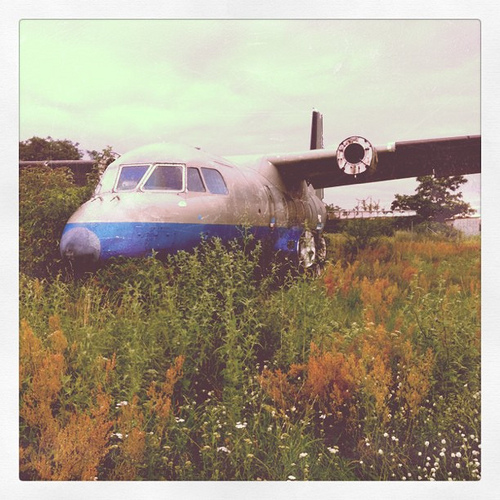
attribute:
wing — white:
[256, 125, 491, 203]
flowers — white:
[436, 453, 446, 459]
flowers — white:
[446, 450, 456, 456]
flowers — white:
[421, 459, 426, 472]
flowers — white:
[471, 457, 475, 465]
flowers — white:
[235, 421, 245, 431]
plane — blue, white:
[24, 107, 471, 266]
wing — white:
[258, 101, 486, 219]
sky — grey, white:
[20, 20, 474, 155]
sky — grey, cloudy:
[19, 18, 481, 217]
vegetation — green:
[23, 246, 470, 470]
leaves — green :
[391, 176, 472, 218]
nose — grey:
[40, 207, 132, 289]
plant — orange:
[260, 316, 440, 443]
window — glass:
[140, 166, 227, 196]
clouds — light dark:
[100, 48, 410, 107]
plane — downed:
[37, 51, 407, 332]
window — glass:
[130, 163, 185, 201]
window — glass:
[181, 162, 225, 198]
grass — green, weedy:
[17, 247, 274, 409]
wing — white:
[282, 120, 477, 190]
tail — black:
[303, 110, 334, 216]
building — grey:
[331, 207, 478, 242]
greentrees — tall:
[26, 127, 115, 272]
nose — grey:
[52, 217, 107, 282]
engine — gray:
[335, 137, 380, 180]